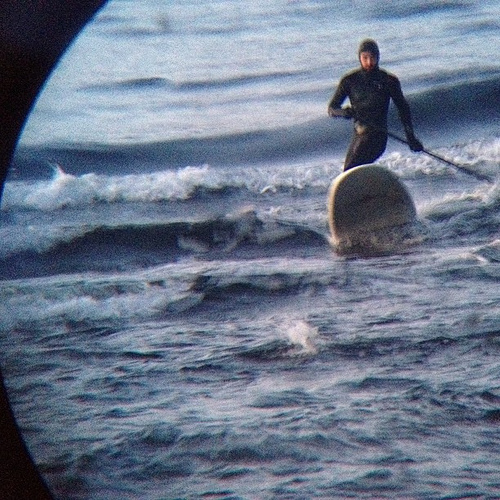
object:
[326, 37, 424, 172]
man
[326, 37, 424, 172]
wet suit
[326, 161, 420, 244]
board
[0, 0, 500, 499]
water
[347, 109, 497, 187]
paddle